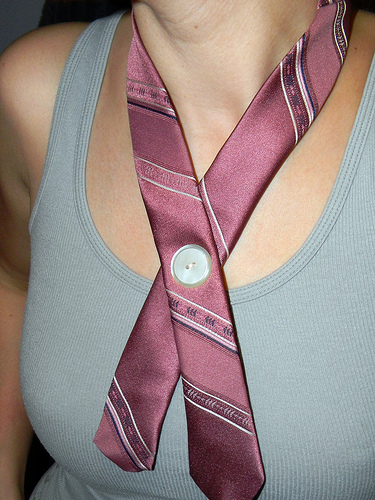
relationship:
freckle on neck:
[186, 18, 205, 37] [110, 7, 362, 69]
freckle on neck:
[192, 22, 200, 30] [120, 3, 361, 97]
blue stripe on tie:
[105, 402, 143, 470] [96, 3, 359, 498]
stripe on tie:
[183, 395, 253, 437] [91, 2, 295, 483]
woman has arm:
[1, 6, 370, 496] [0, 121, 28, 499]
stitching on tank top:
[72, 12, 374, 307] [14, 3, 373, 499]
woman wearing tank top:
[1, 6, 370, 496] [17, 10, 374, 498]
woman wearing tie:
[1, 6, 370, 496] [96, 3, 359, 498]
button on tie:
[169, 242, 214, 284] [96, 3, 359, 498]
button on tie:
[170, 242, 213, 289] [96, 3, 359, 498]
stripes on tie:
[271, 35, 328, 133] [88, 5, 367, 434]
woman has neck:
[1, 6, 370, 496] [131, 1, 321, 65]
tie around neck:
[111, 74, 288, 336] [130, 0, 319, 85]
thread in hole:
[184, 252, 196, 272] [184, 262, 190, 269]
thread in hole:
[184, 252, 196, 272] [190, 260, 197, 266]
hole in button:
[184, 262, 190, 269] [169, 243, 213, 287]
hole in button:
[190, 260, 197, 266] [169, 243, 213, 287]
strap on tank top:
[33, 38, 105, 148] [35, 61, 374, 446]